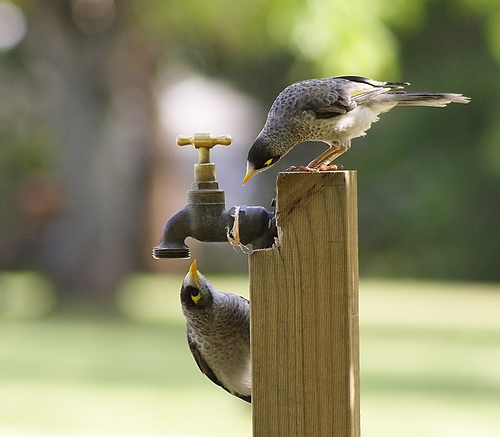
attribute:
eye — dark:
[174, 270, 238, 302]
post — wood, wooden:
[243, 161, 362, 435]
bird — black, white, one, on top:
[236, 73, 488, 191]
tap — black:
[153, 129, 270, 261]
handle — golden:
[177, 130, 231, 160]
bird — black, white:
[183, 261, 246, 411]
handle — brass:
[144, 122, 276, 258]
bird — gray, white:
[241, 71, 423, 151]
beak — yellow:
[241, 151, 268, 185]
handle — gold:
[175, 127, 240, 182]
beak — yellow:
[187, 258, 202, 275]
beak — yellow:
[243, 164, 260, 182]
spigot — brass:
[173, 131, 233, 174]